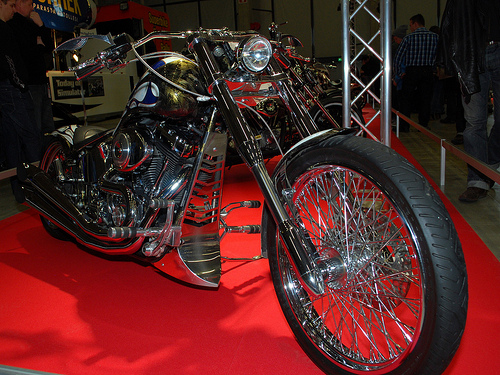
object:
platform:
[3, 98, 494, 366]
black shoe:
[460, 182, 490, 204]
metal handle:
[54, 29, 189, 80]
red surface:
[29, 291, 69, 323]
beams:
[333, 0, 394, 137]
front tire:
[266, 133, 468, 373]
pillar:
[339, 0, 391, 146]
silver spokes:
[295, 179, 400, 349]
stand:
[107, 224, 169, 241]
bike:
[13, 19, 466, 372]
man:
[393, 12, 437, 130]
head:
[408, 13, 426, 31]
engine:
[83, 112, 200, 229]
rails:
[386, 100, 422, 131]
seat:
[73, 120, 122, 141]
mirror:
[47, 31, 92, 64]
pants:
[401, 67, 434, 129]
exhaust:
[12, 162, 159, 259]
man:
[442, 0, 500, 208]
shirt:
[393, 27, 450, 73]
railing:
[393, 113, 494, 185]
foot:
[459, 182, 491, 204]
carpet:
[0, 130, 497, 372]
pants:
[455, 73, 500, 188]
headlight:
[240, 36, 271, 71]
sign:
[32, 0, 92, 31]